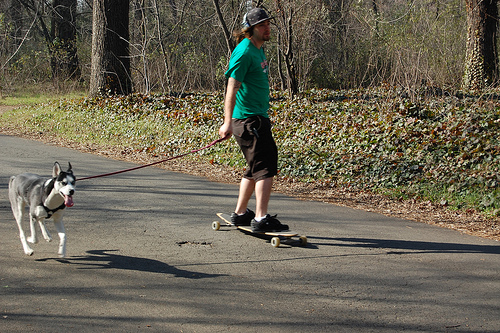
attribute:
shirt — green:
[224, 31, 271, 122]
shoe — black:
[249, 212, 290, 232]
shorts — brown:
[228, 118, 282, 183]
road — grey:
[0, 132, 499, 331]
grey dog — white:
[8, 159, 78, 258]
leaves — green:
[332, 115, 496, 197]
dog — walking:
[4, 154, 95, 269]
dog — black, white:
[3, 157, 78, 264]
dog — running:
[5, 154, 86, 263]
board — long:
[213, 206, 296, 234]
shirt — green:
[219, 41, 276, 123]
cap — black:
[239, 1, 271, 37]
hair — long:
[226, 19, 275, 48]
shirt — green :
[221, 39, 282, 119]